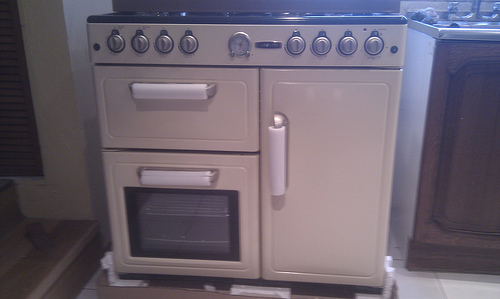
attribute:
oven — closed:
[102, 176, 244, 259]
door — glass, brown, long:
[107, 156, 230, 196]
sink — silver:
[426, 3, 493, 37]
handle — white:
[118, 68, 223, 124]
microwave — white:
[92, 136, 258, 261]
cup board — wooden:
[111, 283, 346, 295]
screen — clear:
[188, 194, 231, 218]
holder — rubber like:
[249, 104, 298, 195]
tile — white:
[405, 271, 449, 287]